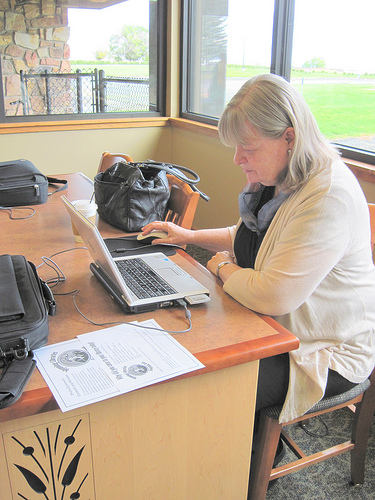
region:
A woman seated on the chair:
[217, 93, 354, 296]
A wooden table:
[183, 319, 263, 380]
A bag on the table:
[80, 161, 170, 218]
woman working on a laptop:
[137, 71, 373, 418]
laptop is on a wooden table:
[59, 195, 213, 313]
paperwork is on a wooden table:
[23, 318, 206, 410]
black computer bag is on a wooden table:
[1, 159, 71, 208]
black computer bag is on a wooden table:
[1, 247, 56, 410]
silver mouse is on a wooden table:
[134, 226, 168, 244]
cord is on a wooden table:
[36, 241, 192, 334]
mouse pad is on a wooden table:
[104, 234, 176, 255]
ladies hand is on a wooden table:
[139, 219, 195, 250]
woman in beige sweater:
[210, 98, 357, 357]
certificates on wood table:
[32, 316, 206, 415]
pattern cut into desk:
[5, 410, 106, 485]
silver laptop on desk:
[53, 204, 214, 314]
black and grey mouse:
[135, 220, 176, 256]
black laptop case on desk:
[1, 246, 55, 404]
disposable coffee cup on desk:
[65, 193, 107, 253]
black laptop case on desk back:
[2, 147, 64, 217]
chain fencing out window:
[17, 48, 163, 143]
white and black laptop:
[65, 196, 216, 312]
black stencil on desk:
[9, 431, 96, 499]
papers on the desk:
[33, 324, 191, 411]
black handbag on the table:
[91, 149, 211, 232]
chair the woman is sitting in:
[259, 200, 369, 498]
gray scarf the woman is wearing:
[231, 177, 282, 235]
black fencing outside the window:
[9, 67, 145, 112]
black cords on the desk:
[4, 205, 200, 343]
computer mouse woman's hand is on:
[134, 225, 172, 244]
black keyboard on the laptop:
[122, 253, 167, 298]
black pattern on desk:
[8, 434, 45, 466]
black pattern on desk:
[6, 449, 56, 498]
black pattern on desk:
[51, 425, 75, 461]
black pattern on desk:
[57, 419, 90, 466]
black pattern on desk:
[53, 447, 81, 495]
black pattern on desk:
[43, 430, 61, 488]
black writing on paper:
[58, 342, 91, 373]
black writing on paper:
[124, 356, 150, 380]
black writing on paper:
[81, 335, 117, 368]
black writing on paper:
[63, 368, 85, 403]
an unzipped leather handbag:
[87, 150, 207, 230]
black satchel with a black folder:
[0, 248, 54, 362]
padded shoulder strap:
[0, 355, 38, 410]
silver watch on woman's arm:
[213, 255, 228, 275]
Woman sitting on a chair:
[140, 73, 374, 498]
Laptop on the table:
[0, 170, 300, 498]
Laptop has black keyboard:
[58, 193, 210, 315]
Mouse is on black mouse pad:
[100, 226, 176, 255]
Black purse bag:
[88, 156, 210, 233]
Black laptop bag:
[0, 253, 57, 411]